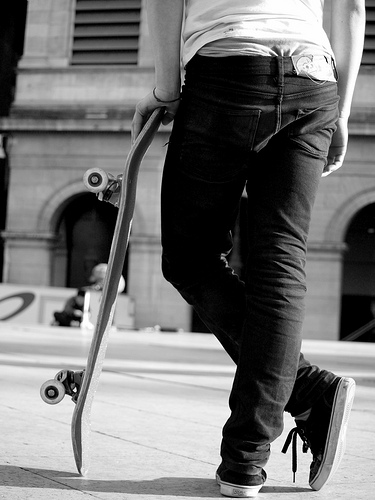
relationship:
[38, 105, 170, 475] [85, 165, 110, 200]
skateboard has wheel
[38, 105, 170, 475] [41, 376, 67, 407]
skateboard has wheel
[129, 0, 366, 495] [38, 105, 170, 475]
person at skateboard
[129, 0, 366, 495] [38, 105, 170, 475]
person holding skateboard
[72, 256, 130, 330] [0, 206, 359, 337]
person in distance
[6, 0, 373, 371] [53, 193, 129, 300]
building has door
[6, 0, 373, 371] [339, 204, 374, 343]
building has door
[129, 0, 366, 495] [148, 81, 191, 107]
person has wrist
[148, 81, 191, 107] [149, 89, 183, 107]
wrist has bracelet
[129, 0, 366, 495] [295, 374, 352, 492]
person wearing shoe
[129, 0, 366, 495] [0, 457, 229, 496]
person casting shadow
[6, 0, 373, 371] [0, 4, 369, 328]
building in background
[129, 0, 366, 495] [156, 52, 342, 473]
person wearing trousers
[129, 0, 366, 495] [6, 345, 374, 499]
person in sidewalk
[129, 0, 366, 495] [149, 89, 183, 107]
person wearing bracelet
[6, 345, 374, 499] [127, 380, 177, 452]
floor has a part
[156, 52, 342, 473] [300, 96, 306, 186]
trousers has a part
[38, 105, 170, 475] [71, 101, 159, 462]
skateboard has edge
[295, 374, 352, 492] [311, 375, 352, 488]
shoe has sole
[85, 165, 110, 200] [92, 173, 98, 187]
wheel has a part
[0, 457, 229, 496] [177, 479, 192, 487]
shadow has a part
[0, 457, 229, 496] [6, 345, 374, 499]
shadow on floor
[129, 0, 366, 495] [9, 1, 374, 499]
person in photo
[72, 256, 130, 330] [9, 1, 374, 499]
person in photo